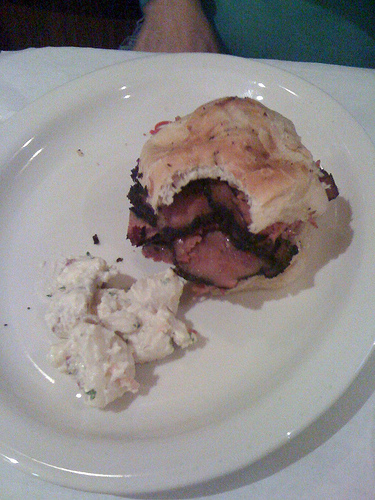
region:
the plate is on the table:
[2, 0, 363, 490]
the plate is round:
[0, 47, 355, 461]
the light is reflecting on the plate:
[0, 430, 137, 494]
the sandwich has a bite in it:
[137, 75, 330, 293]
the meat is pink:
[139, 177, 311, 292]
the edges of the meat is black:
[171, 180, 299, 281]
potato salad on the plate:
[39, 226, 195, 389]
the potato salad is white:
[7, 228, 210, 408]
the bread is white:
[120, 96, 335, 270]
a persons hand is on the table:
[115, 1, 356, 63]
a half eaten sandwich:
[139, 92, 284, 282]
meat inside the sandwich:
[159, 165, 242, 280]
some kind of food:
[40, 242, 171, 381]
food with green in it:
[47, 263, 161, 394]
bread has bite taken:
[143, 112, 325, 256]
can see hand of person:
[129, 11, 230, 64]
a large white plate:
[205, 295, 318, 427]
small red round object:
[149, 115, 172, 143]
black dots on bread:
[173, 105, 275, 181]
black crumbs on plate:
[58, 225, 128, 268]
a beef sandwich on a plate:
[121, 92, 322, 294]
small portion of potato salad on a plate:
[45, 258, 173, 393]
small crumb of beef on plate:
[91, 231, 100, 246]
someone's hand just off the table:
[133, 3, 225, 59]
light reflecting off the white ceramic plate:
[16, 134, 40, 158]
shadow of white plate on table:
[284, 390, 371, 442]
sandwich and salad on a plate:
[10, 73, 354, 416]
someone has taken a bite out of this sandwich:
[126, 120, 317, 282]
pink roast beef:
[109, 160, 340, 307]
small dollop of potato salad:
[42, 250, 209, 419]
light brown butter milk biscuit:
[131, 84, 344, 239]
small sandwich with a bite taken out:
[115, 83, 348, 302]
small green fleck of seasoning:
[82, 383, 100, 406]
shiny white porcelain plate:
[2, 47, 372, 495]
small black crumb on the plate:
[82, 225, 104, 251]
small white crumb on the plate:
[68, 141, 84, 161]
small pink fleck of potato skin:
[52, 256, 84, 267]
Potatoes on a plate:
[42, 249, 191, 409]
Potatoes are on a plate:
[37, 253, 195, 407]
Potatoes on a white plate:
[43, 251, 198, 408]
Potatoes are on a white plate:
[41, 253, 201, 407]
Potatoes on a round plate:
[50, 252, 197, 409]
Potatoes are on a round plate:
[44, 253, 199, 409]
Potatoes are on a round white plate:
[39, 253, 200, 412]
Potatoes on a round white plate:
[38, 250, 204, 408]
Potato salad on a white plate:
[43, 250, 203, 411]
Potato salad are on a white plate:
[41, 251, 198, 411]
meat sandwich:
[130, 83, 325, 283]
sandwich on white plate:
[141, 90, 336, 296]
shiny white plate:
[136, 415, 207, 455]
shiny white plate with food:
[55, 91, 321, 363]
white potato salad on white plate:
[52, 324, 132, 404]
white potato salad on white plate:
[50, 252, 100, 306]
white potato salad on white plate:
[131, 287, 184, 352]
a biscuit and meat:
[128, 98, 338, 290]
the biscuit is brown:
[137, 97, 328, 234]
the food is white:
[49, 258, 204, 399]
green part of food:
[87, 389, 99, 401]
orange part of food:
[188, 326, 200, 336]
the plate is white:
[1, 50, 372, 494]